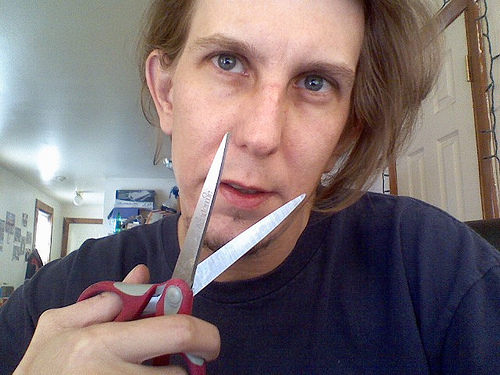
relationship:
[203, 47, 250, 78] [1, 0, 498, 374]
eye on man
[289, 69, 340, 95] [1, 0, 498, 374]
eye on man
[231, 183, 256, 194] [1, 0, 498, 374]
teeth on man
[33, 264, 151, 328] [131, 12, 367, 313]
finger on man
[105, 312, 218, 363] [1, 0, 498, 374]
finger on man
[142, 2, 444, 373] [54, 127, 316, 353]
man holding scissors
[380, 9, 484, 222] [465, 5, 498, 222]
door with trim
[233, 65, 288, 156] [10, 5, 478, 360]
nose of a woman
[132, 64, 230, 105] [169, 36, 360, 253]
ears of a woman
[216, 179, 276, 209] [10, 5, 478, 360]
lips of a woman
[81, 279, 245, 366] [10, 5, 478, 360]
finger of a woman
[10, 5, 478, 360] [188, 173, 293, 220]
woman has teeth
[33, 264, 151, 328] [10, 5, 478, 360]
finger on woman